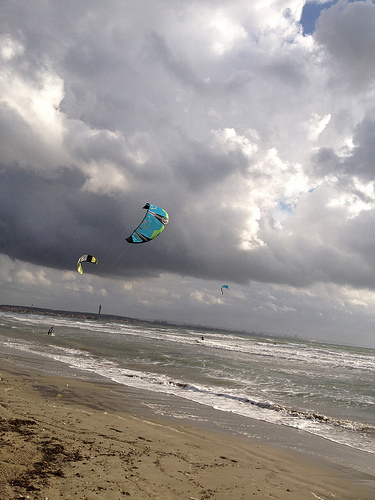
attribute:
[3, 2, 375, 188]
clouds — black, big, grey, thick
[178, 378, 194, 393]
wave — forming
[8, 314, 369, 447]
ocean — beautiful, rough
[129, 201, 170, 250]
parachute — blue, colorful, flying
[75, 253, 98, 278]
parachute — bright, yellow, grey, black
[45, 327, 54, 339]
person — standing, playing, far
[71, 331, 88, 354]
water — cold, vast, grey, foamy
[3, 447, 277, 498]
sand — beautiful, beige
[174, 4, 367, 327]
sky — cloudy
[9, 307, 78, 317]
land — far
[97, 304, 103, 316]
light house — distant, far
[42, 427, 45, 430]
cap — small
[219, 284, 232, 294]
sail — blue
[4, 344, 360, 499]
beach — sandy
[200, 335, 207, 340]
surfer — far